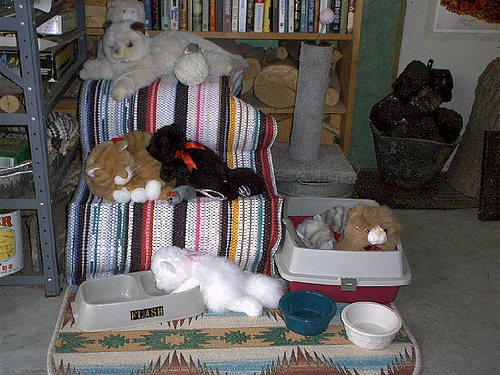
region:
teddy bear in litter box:
[283, 191, 427, 284]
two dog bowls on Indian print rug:
[274, 288, 406, 351]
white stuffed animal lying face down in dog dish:
[59, 251, 285, 328]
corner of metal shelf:
[8, 10, 83, 310]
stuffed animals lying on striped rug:
[86, 3, 284, 238]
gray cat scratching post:
[268, 5, 356, 190]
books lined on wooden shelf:
[148, 3, 370, 41]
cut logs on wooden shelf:
[256, 46, 343, 113]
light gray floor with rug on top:
[6, 212, 487, 373]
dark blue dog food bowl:
[274, 288, 334, 337]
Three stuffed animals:
[78, 0, 263, 204]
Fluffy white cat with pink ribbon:
[147, 240, 284, 318]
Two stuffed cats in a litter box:
[275, 190, 417, 307]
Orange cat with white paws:
[83, 124, 175, 203]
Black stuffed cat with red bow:
[145, 116, 265, 199]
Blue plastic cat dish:
[277, 288, 334, 338]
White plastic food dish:
[340, 300, 403, 350]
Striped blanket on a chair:
[62, 62, 287, 283]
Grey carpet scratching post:
[269, 7, 359, 188]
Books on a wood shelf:
[141, 1, 356, 33]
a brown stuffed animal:
[342, 201, 401, 265]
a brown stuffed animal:
[146, 117, 263, 209]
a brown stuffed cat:
[81, 130, 161, 205]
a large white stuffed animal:
[76, 15, 247, 103]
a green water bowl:
[271, 281, 337, 335]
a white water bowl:
[334, 297, 404, 354]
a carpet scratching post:
[267, 9, 363, 190]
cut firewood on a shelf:
[228, 28, 343, 109]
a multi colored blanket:
[73, 67, 283, 282]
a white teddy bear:
[152, 228, 299, 342]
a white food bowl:
[333, 298, 404, 356]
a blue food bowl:
[269, 284, 337, 347]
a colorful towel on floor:
[1, 333, 477, 373]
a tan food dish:
[43, 255, 215, 356]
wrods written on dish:
[116, 295, 169, 330]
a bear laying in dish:
[136, 237, 215, 311]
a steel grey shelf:
[0, 122, 61, 291]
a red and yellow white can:
[0, 205, 47, 317]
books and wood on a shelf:
[211, 1, 386, 102]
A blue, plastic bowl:
[270, 281, 338, 338]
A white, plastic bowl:
[336, 293, 399, 358]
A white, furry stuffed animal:
[146, 237, 286, 317]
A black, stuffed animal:
[141, 120, 267, 212]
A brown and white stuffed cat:
[70, 113, 174, 211]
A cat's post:
[253, 23, 385, 198]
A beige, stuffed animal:
[66, 16, 263, 116]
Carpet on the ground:
[424, 226, 489, 353]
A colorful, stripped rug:
[76, 216, 241, 254]